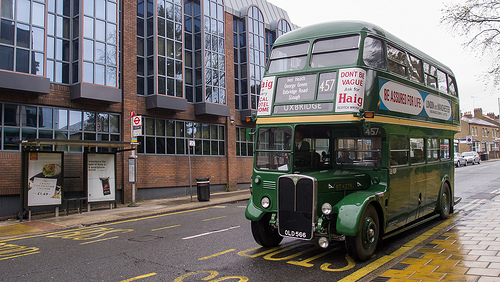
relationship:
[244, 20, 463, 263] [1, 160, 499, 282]
bus on street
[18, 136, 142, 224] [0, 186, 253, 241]
bus stop on sidewalk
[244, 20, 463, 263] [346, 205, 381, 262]
bus has wheel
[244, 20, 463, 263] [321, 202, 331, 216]
bus has headlight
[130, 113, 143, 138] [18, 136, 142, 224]
sign next to bus stop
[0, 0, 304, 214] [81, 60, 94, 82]
building has window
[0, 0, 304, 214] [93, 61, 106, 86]
building has window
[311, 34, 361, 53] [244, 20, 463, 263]
window on bus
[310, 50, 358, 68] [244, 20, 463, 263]
window on bus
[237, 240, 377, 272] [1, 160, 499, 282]
word on street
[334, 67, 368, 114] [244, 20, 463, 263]
advertisement on bus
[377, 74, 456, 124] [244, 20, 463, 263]
advertisement on bus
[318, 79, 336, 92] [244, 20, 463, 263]
number on bus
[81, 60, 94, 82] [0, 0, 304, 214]
window on building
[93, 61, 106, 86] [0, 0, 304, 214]
window on building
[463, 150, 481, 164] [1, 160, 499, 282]
car on street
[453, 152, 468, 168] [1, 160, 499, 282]
car on street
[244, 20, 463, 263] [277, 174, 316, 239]
bus has grill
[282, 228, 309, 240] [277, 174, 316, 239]
number on grill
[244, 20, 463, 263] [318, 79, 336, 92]
bus has number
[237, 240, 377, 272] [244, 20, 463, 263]
word under bus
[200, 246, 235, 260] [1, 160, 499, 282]
line in street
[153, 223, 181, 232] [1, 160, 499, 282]
line on street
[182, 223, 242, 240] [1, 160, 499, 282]
line on street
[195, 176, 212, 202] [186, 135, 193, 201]
trash can next to pole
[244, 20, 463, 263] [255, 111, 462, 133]
bus has stripe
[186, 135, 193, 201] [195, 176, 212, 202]
pole near trash can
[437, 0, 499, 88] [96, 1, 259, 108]
tree has reflection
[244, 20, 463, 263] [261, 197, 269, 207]
bus has headlight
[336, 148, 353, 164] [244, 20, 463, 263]
passenger on bus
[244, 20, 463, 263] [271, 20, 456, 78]
bus has roof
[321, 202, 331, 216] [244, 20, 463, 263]
headlight on bus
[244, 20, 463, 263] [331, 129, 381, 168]
bus has windshield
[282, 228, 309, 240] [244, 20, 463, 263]
number on bus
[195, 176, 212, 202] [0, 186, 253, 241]
trash can on sidewalk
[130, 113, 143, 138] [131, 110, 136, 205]
sign on pole